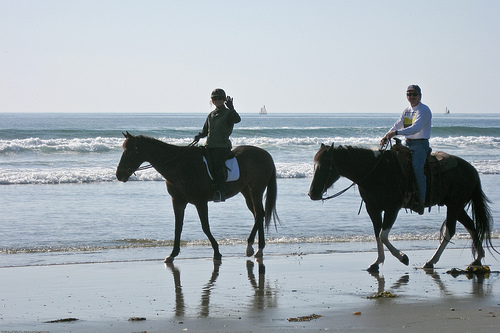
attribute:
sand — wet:
[0, 242, 499, 330]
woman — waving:
[192, 88, 241, 203]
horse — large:
[116, 130, 279, 267]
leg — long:
[192, 200, 221, 261]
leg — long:
[166, 195, 188, 264]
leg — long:
[250, 181, 265, 257]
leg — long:
[242, 187, 255, 257]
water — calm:
[0, 112, 499, 258]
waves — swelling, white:
[1, 137, 499, 193]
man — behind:
[383, 85, 432, 214]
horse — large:
[308, 142, 497, 274]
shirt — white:
[387, 106, 431, 139]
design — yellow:
[402, 117, 415, 125]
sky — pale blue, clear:
[0, 1, 499, 113]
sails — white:
[260, 105, 266, 112]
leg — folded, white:
[378, 203, 410, 266]